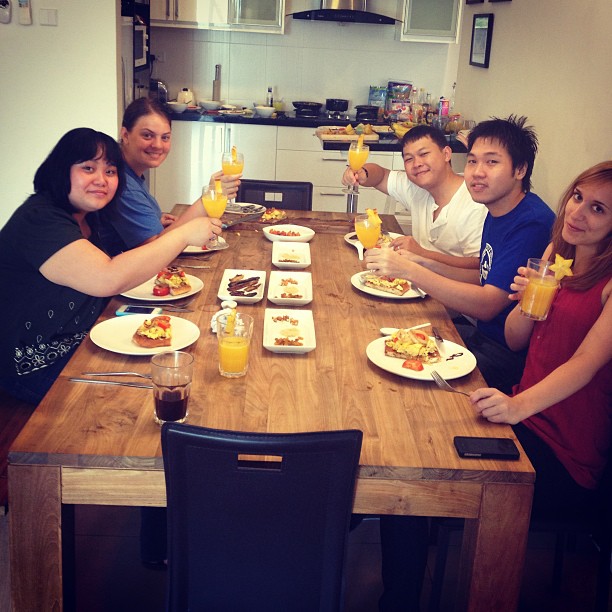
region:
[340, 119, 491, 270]
man holding up his glass in a toast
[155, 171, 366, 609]
two empty seats facing each other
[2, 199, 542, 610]
natural wood dining table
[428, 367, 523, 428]
hand holding a fork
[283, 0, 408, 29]
modernistic shaped range hood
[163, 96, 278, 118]
plates and bowls on sink counter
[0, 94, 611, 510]
people toasting a meal with glasses of orange juice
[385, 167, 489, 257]
unbuttoned white short sleeve shirt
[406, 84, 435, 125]
three bottles of sauce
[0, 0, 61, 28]
three wall mounted electrical devices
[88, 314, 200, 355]
a white plate with food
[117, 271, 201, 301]
a white plate with food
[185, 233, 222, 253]
a white plate with food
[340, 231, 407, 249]
a white plate with food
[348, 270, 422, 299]
a white plate with food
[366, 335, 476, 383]
a white plate with food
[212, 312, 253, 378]
a clear glass of orange juice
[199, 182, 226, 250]
a clear glass of orange juice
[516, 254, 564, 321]
a clear glass of orange juice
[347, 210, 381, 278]
a clear glass of orange juice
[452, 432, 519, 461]
the phone is black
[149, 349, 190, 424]
the glass has brown liquid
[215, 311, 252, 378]
the orange juice in the glass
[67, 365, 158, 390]
the utensils are silver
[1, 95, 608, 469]
the people sitting at the table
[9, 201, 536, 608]
the table is made of wood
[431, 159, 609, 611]
the woman is sitting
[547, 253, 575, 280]
the fruit is shaped like a star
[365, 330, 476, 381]
the food on the plate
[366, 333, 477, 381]
the plate is white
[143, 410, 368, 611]
The empty chair on the near side of the table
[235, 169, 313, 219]
The empty chair on the far side of the table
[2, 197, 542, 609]
The table the people are sitting around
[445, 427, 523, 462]
Black phone at the edge of the table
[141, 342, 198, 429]
The glass with the dark colored drink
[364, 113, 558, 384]
The man in the blue shirt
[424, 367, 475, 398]
The fork held by the woman in pink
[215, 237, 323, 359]
The rectangular dishes in the middle of the table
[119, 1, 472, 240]
The kitchen beyond the table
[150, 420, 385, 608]
A black chair at a table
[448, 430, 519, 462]
A cell phone on a table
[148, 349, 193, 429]
A glass with liquid in it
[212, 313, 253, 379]
A glass with juice in it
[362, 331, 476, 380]
A white plate with food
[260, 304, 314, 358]
A tray with food in it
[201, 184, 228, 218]
A wine glass with juice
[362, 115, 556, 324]
A man in a blue shirt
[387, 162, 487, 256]
A man in a white shirt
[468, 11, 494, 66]
A framed picture on a wall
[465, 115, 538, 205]
head with spiky black hair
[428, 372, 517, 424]
fork handle in hand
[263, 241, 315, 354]
three identical white dishes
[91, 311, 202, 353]
food on white plate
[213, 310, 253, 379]
orange liquid in drinking glass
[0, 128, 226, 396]
woman holding up glass for toast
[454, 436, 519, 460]
black cell phone with blank screen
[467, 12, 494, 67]
picture in black frame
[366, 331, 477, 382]
round plate is white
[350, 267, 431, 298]
round plate is white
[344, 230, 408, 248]
round plate is white